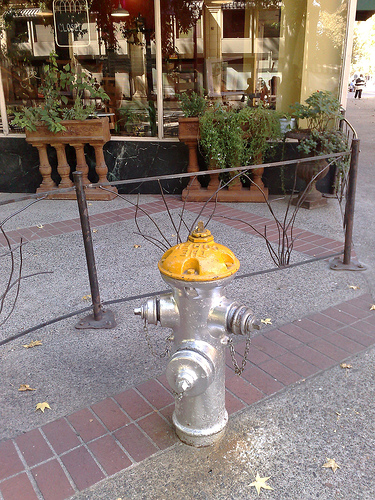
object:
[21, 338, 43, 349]
leaf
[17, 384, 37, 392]
leaf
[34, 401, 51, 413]
leaf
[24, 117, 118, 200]
holder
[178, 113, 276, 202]
holder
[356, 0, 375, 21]
awning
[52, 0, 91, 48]
sign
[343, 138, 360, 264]
post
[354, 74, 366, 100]
person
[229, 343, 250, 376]
chain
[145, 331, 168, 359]
chain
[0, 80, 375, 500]
ground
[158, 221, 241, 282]
cover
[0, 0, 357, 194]
wall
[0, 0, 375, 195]
building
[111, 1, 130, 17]
hanging light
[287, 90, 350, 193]
planter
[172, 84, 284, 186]
planter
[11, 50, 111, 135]
planter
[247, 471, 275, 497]
leaf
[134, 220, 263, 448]
fire hydrant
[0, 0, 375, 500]
street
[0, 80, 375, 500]
sidewalk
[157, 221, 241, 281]
top